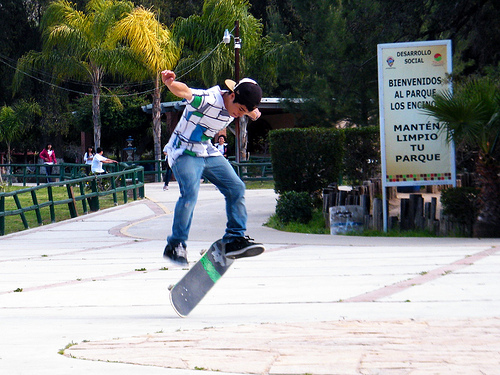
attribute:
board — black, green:
[166, 237, 242, 320]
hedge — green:
[267, 124, 382, 194]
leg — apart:
[216, 160, 253, 239]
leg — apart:
[163, 163, 199, 235]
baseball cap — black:
[223, 76, 258, 108]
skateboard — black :
[164, 234, 239, 316]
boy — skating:
[153, 57, 276, 272]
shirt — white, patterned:
[107, 53, 342, 326]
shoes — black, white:
[159, 239, 194, 271]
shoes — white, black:
[222, 230, 264, 260]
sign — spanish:
[369, 33, 469, 197]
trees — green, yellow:
[12, 1, 266, 173]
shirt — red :
[36, 148, 51, 163]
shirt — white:
[161, 85, 234, 169]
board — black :
[166, 234, 232, 319]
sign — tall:
[374, 38, 457, 234]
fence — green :
[0, 162, 145, 235]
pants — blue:
[170, 154, 245, 245]